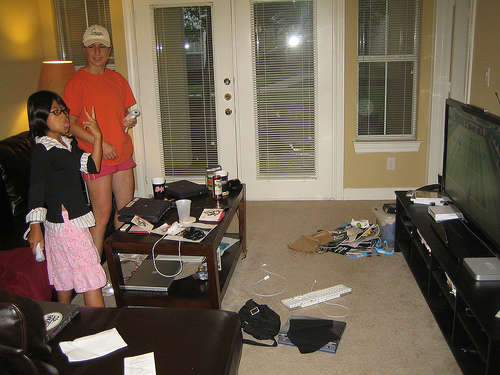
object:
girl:
[23, 86, 107, 307]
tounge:
[65, 123, 72, 128]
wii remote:
[32, 244, 46, 263]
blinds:
[254, 3, 322, 179]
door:
[253, 4, 315, 178]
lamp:
[33, 59, 81, 96]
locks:
[223, 77, 232, 86]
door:
[126, 0, 237, 187]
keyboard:
[281, 276, 352, 311]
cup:
[175, 196, 193, 227]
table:
[99, 170, 250, 310]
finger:
[78, 108, 91, 119]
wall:
[3, 4, 59, 140]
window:
[149, 0, 220, 184]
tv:
[440, 90, 499, 250]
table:
[389, 184, 499, 344]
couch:
[2, 129, 70, 261]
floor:
[374, 273, 401, 339]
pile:
[286, 215, 391, 261]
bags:
[236, 292, 284, 349]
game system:
[427, 203, 458, 222]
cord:
[249, 262, 293, 299]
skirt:
[38, 219, 111, 293]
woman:
[61, 21, 144, 258]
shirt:
[66, 66, 138, 164]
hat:
[81, 24, 112, 46]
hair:
[23, 90, 67, 138]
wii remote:
[121, 109, 141, 133]